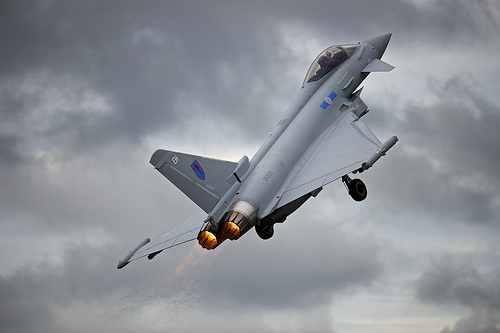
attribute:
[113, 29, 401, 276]
plane — grey 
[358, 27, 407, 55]
plane's nose — grey 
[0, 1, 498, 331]
sky — dark 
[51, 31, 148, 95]
clouds — dark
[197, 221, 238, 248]
lights — red